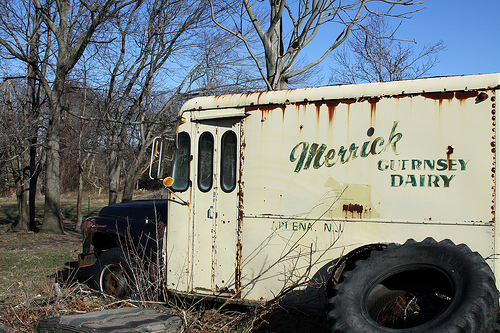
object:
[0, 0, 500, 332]
wooded area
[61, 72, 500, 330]
dairy truck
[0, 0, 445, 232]
trees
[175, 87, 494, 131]
rust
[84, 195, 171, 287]
paint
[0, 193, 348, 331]
weeds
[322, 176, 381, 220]
cow shape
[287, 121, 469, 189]
green logo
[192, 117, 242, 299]
door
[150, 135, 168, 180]
mirror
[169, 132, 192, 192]
windows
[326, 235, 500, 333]
tire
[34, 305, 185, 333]
rock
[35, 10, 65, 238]
tree trunk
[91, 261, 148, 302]
tire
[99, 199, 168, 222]
hood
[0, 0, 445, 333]
branch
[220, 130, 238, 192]
window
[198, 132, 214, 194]
window